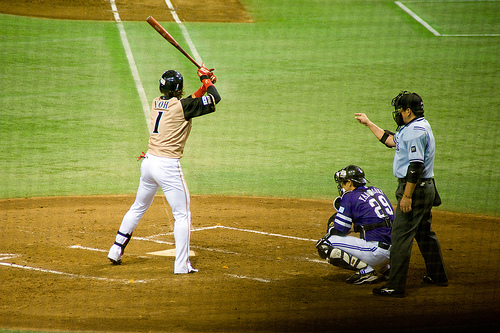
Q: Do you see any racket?
A: No, there are no rackets.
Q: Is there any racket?
A: No, there are no rackets.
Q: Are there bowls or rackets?
A: No, there are no rackets or bowls.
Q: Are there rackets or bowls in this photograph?
A: No, there are no rackets or bowls.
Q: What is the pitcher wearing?
A: The pitcher is wearing a shoe.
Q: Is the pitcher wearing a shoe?
A: Yes, the pitcher is wearing a shoe.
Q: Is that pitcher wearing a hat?
A: No, the pitcher is wearing a shoe.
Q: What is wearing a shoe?
A: The pitcher is wearing a shoe.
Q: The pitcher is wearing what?
A: The pitcher is wearing a shoe.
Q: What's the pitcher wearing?
A: The pitcher is wearing a shoe.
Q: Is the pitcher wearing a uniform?
A: No, the pitcher is wearing a shoe.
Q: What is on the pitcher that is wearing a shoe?
A: The face mask is on the pitcher.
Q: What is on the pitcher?
A: The face mask is on the pitcher.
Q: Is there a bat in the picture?
A: Yes, there is a bat.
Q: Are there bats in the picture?
A: Yes, there is a bat.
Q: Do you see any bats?
A: Yes, there is a bat.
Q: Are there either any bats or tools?
A: Yes, there is a bat.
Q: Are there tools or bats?
A: Yes, there is a bat.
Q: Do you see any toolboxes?
A: No, there are no toolboxes.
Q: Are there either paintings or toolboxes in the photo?
A: No, there are no toolboxes or paintings.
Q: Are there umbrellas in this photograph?
A: No, there are no umbrellas.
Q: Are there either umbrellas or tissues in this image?
A: No, there are no umbrellas or tissues.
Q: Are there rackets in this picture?
A: No, there are no rackets.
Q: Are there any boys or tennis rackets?
A: No, there are no tennis rackets or boys.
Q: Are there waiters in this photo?
A: No, there are no waiters.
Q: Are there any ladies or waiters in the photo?
A: No, there are no waiters or ladies.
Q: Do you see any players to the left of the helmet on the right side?
A: Yes, there is a player to the left of the helmet.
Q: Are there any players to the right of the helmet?
A: No, the player is to the left of the helmet.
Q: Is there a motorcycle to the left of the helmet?
A: No, there is a player to the left of the helmet.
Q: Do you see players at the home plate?
A: Yes, there is a player at the home plate.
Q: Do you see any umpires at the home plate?
A: No, there is a player at the home plate.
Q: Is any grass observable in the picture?
A: Yes, there is grass.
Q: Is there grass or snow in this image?
A: Yes, there is grass.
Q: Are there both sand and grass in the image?
A: No, there is grass but no sand.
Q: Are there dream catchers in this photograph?
A: No, there are no dream catchers.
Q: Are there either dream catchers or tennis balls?
A: No, there are no dream catchers or tennis balls.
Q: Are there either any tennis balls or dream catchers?
A: No, there are no dream catchers or tennis balls.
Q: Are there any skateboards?
A: No, there are no skateboards.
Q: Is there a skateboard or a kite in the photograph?
A: No, there are no skateboards or kites.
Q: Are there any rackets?
A: No, there are no rackets.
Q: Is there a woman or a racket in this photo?
A: No, there are no rackets or women.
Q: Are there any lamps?
A: No, there are no lamps.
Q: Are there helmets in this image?
A: Yes, there is a helmet.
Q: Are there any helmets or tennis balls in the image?
A: Yes, there is a helmet.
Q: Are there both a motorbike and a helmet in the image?
A: No, there is a helmet but no motorcycles.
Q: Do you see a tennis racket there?
A: No, there are no rackets.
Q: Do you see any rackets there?
A: No, there are no rackets.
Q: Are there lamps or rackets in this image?
A: No, there are no rackets or lamps.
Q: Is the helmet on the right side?
A: Yes, the helmet is on the right of the image.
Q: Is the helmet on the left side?
A: No, the helmet is on the right of the image.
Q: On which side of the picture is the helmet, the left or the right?
A: The helmet is on the right of the image.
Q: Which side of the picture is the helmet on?
A: The helmet is on the right of the image.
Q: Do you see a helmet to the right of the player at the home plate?
A: Yes, there is a helmet to the right of the player.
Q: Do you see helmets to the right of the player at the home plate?
A: Yes, there is a helmet to the right of the player.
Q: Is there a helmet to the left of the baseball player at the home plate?
A: No, the helmet is to the right of the player.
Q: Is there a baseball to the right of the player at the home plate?
A: No, there is a helmet to the right of the player.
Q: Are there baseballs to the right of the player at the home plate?
A: No, there is a helmet to the right of the player.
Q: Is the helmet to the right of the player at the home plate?
A: Yes, the helmet is to the right of the player.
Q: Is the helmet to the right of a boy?
A: No, the helmet is to the right of the player.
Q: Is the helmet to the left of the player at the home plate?
A: No, the helmet is to the right of the player.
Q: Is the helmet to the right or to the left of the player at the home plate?
A: The helmet is to the right of the player.